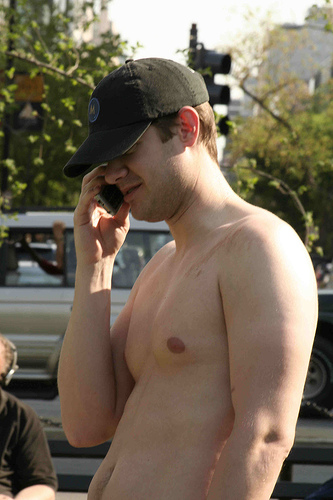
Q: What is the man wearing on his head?
A: Hat.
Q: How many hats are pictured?
A: One.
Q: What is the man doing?
A: Talking on phone.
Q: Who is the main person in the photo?
A: A man.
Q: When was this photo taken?
A: During the day.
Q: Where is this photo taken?
A: In a town.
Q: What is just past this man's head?
A: Stop light.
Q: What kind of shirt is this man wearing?
A: None.